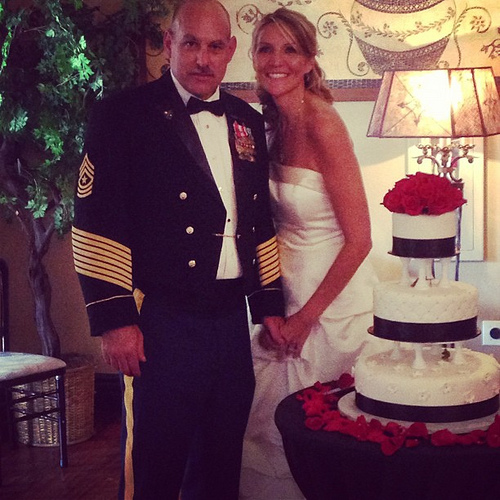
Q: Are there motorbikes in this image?
A: No, there are no motorbikes.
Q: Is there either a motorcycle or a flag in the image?
A: No, there are no motorcycles or flags.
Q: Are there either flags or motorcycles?
A: No, there are no motorcycles or flags.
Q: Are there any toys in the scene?
A: No, there are no toys.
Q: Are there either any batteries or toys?
A: No, there are no toys or batteries.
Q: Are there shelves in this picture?
A: No, there are no shelves.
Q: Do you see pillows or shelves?
A: No, there are no shelves or pillows.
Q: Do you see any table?
A: Yes, there is a table.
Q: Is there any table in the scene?
A: Yes, there is a table.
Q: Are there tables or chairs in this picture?
A: Yes, there is a table.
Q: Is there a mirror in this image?
A: No, there are no mirrors.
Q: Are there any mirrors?
A: No, there are no mirrors.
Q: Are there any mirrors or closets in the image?
A: No, there are no mirrors or closets.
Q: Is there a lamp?
A: Yes, there is a lamp.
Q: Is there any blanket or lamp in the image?
A: Yes, there is a lamp.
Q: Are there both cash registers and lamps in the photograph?
A: No, there is a lamp but no cash registers.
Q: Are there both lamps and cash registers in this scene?
A: No, there is a lamp but no cash registers.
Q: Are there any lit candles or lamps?
A: Yes, there is a lit lamp.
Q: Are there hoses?
A: No, there are no hoses.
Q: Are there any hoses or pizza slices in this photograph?
A: No, there are no hoses or pizza slices.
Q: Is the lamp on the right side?
A: Yes, the lamp is on the right of the image.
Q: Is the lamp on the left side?
A: No, the lamp is on the right of the image.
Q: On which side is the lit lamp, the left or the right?
A: The lamp is on the right of the image.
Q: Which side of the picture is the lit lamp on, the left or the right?
A: The lamp is on the right of the image.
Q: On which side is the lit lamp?
A: The lamp is on the right of the image.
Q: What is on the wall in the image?
A: The lamp is on the wall.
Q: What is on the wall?
A: The lamp is on the wall.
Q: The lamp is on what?
A: The lamp is on the wall.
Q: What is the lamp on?
A: The lamp is on the wall.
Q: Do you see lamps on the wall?
A: Yes, there is a lamp on the wall.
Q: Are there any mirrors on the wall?
A: No, there is a lamp on the wall.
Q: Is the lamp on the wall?
A: Yes, the lamp is on the wall.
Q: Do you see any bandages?
A: No, there are no bandages.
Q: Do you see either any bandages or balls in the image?
A: No, there are no bandages or balls.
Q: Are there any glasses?
A: No, there are no glasses.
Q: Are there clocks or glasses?
A: No, there are no glasses or clocks.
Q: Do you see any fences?
A: No, there are no fences.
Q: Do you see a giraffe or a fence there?
A: No, there are no fences or giraffes.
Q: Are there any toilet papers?
A: No, there are no toilet papers.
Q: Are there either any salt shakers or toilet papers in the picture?
A: No, there are no toilet papers or salt shakers.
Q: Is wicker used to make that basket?
A: Yes, the basket is made of wicker.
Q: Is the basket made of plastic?
A: No, the basket is made of wicker.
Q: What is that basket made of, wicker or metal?
A: The basket is made of wicker.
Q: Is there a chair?
A: Yes, there is a chair.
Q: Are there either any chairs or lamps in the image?
A: Yes, there is a chair.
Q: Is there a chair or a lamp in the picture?
A: Yes, there is a chair.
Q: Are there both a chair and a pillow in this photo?
A: No, there is a chair but no pillows.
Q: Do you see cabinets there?
A: No, there are no cabinets.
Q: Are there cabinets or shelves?
A: No, there are no cabinets or shelves.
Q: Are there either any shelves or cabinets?
A: No, there are no cabinets or shelves.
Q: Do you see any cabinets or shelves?
A: No, there are no cabinets or shelves.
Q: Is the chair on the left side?
A: Yes, the chair is on the left of the image.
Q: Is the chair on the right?
A: No, the chair is on the left of the image.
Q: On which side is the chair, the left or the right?
A: The chair is on the left of the image.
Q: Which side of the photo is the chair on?
A: The chair is on the left of the image.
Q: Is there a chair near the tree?
A: Yes, there is a chair near the tree.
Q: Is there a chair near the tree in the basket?
A: Yes, there is a chair near the tree.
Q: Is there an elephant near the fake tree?
A: No, there is a chair near the tree.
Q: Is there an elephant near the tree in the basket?
A: No, there is a chair near the tree.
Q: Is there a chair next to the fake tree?
A: Yes, there is a chair next to the tree.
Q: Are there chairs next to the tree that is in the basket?
A: Yes, there is a chair next to the tree.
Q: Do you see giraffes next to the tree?
A: No, there is a chair next to the tree.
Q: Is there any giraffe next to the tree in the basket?
A: No, there is a chair next to the tree.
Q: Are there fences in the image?
A: No, there are no fences.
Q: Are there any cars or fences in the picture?
A: No, there are no fences or cars.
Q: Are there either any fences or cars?
A: No, there are no fences or cars.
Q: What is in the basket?
A: The tree is in the basket.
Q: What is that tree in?
A: The tree is in the basket.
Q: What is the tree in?
A: The tree is in the basket.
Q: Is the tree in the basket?
A: Yes, the tree is in the basket.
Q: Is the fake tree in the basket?
A: Yes, the tree is in the basket.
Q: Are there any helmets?
A: No, there are no helmets.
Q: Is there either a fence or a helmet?
A: No, there are no helmets or fences.